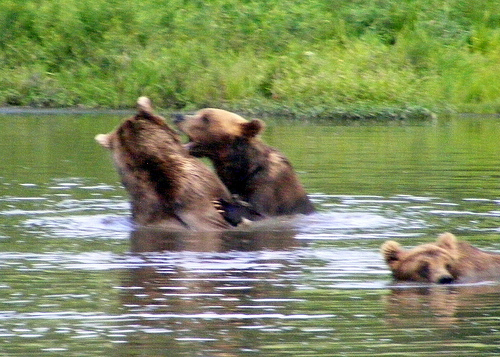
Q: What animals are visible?
A: Bears.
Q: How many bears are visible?
A: 3.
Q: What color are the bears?
A: Brown.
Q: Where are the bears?
A: In water.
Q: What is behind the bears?
A: Bushes.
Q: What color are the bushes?
A: Green.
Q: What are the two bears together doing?
A: Playing.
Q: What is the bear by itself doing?
A: Swimming.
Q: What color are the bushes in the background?
A: Green.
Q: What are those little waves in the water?
A: Ripples.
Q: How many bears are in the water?
A: Three.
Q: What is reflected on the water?
A: The bears.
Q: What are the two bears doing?
A: Play fighting.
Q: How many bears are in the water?
A: Three.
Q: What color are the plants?
A: Green.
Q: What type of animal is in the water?
A: Bears.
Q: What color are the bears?
A: Brown.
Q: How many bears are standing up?
A: Two.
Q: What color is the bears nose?
A: Black.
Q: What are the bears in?
A: Water.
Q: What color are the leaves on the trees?
A: Green.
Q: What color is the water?
A: Blue.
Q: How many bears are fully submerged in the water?
A: One.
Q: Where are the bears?
A: In the water.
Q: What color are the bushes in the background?
A: Green.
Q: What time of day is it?
A: Daytime.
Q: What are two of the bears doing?
A: Fighting.